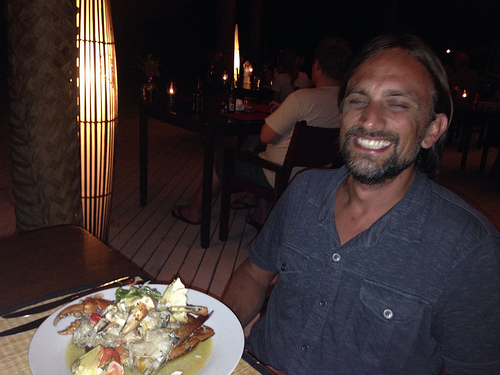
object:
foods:
[52, 275, 216, 373]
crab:
[53, 294, 111, 335]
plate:
[29, 283, 246, 374]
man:
[219, 36, 498, 374]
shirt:
[245, 163, 498, 374]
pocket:
[340, 277, 431, 372]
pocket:
[266, 243, 311, 319]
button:
[331, 252, 342, 263]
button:
[381, 308, 395, 320]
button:
[318, 298, 328, 308]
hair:
[335, 33, 454, 180]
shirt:
[258, 86, 341, 188]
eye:
[347, 97, 367, 106]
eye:
[384, 98, 409, 111]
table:
[0, 223, 280, 374]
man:
[172, 35, 352, 231]